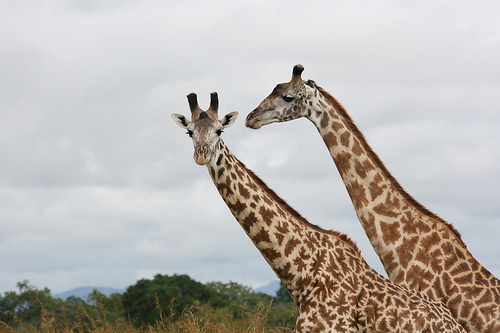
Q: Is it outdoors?
A: Yes, it is outdoors.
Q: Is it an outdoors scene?
A: Yes, it is outdoors.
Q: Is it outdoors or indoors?
A: It is outdoors.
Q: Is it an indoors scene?
A: No, it is outdoors.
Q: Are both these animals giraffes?
A: Yes, all the animals are giraffes.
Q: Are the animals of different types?
A: No, all the animals are giraffes.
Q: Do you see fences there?
A: No, there are no fences.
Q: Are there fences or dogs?
A: No, there are no fences or dogs.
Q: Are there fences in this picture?
A: No, there are no fences.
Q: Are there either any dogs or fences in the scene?
A: No, there are no fences or dogs.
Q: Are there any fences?
A: No, there are no fences.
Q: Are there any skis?
A: No, there are no skis.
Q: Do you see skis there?
A: No, there are no skis.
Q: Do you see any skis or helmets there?
A: No, there are no skis or helmets.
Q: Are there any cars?
A: No, there are no cars.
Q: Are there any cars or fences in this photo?
A: No, there are no cars or fences.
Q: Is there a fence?
A: No, there are no fences.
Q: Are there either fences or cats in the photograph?
A: No, there are no fences or cats.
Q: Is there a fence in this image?
A: No, there are no fences.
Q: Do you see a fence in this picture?
A: No, there are no fences.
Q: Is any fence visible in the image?
A: No, there are no fences.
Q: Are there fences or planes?
A: No, there are no fences or planes.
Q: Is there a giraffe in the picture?
A: Yes, there is a giraffe.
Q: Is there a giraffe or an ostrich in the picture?
A: Yes, there is a giraffe.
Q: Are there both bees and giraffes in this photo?
A: No, there is a giraffe but no bees.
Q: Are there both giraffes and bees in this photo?
A: No, there is a giraffe but no bees.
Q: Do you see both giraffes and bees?
A: No, there is a giraffe but no bees.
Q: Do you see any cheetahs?
A: No, there are no cheetahs.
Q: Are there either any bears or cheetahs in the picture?
A: No, there are no cheetahs or bears.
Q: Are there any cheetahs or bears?
A: No, there are no cheetahs or bears.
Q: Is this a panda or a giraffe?
A: This is a giraffe.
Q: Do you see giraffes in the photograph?
A: Yes, there is a giraffe.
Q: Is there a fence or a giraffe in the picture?
A: Yes, there is a giraffe.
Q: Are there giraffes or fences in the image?
A: Yes, there is a giraffe.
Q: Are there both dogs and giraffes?
A: No, there is a giraffe but no dogs.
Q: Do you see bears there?
A: No, there are no bears.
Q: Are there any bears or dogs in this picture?
A: No, there are no bears or dogs.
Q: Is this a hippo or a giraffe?
A: This is a giraffe.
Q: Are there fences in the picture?
A: No, there are no fences.